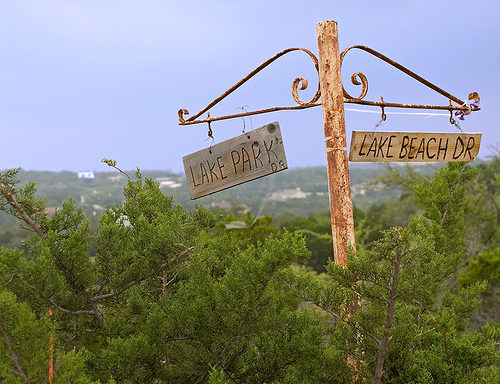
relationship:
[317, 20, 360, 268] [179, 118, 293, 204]
pole has street sign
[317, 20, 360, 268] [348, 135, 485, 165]
pole has street sign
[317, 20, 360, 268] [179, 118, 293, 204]
pole holding street sign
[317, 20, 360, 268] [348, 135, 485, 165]
pole holding street sign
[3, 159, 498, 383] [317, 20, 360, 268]
branches are in front of pole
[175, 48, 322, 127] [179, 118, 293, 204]
rod holding street sign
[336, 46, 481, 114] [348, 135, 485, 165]
rod holding street sign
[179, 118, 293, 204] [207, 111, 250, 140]
street sign has wire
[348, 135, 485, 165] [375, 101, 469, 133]
street sign has wire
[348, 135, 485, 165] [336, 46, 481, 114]
street sign tied to rod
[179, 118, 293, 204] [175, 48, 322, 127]
street sign tied to rod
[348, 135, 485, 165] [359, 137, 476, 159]
street sign has text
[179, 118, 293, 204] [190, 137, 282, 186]
street sign has text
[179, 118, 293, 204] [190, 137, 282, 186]
street sign has name of street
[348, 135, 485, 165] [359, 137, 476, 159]
street sign has name of street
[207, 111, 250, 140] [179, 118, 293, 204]
wire holding street sign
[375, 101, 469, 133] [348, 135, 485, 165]
wire holding street sign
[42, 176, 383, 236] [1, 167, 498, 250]
rocks are in background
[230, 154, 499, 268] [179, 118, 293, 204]
trees are behind street sign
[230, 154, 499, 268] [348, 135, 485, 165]
trees are behind street sign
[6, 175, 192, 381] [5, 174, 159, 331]
tree has leaves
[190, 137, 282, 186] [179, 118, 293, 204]
name of street printed on street sign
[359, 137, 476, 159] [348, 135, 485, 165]
name of street printed on street sign